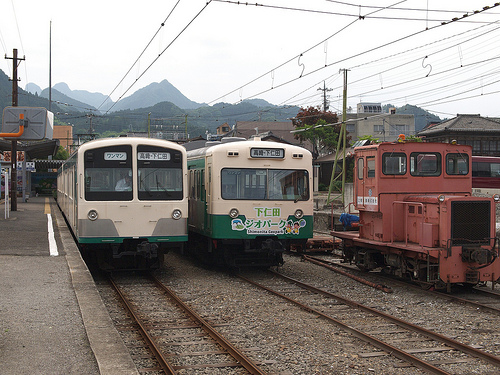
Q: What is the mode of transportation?
A: Train.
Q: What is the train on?
A: Tracks.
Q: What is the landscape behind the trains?
A: Mountains.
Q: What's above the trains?
A: Wires.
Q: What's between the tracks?
A: Gravel.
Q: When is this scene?
A: Afternoon.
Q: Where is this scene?
A: Train station.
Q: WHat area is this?
A: Rural.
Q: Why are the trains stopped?
A: Not in use.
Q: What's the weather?
A: Fair.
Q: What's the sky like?
A: Overcast.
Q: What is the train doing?
A: Leaving the station.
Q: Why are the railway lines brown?
A: They are rusted.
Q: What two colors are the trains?
A: The colors are beige and green.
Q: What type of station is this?
A: Train.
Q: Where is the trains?
A: On tracks.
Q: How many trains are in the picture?
A: 2.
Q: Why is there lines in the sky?
A: For the trains.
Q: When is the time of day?
A: Afternoon.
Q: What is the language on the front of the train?
A: Chinese.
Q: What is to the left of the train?
A: The platform.